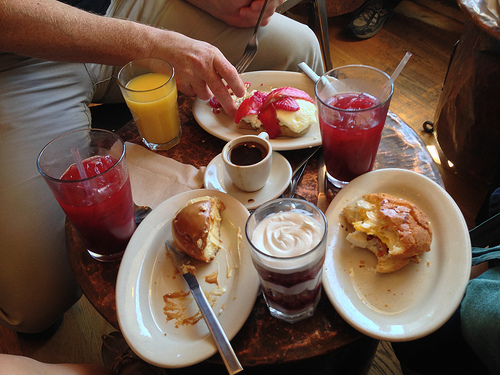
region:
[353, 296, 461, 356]
the plate is white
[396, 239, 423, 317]
the plate is white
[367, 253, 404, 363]
the plate is white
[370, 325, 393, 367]
the plate is white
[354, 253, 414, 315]
the plate is white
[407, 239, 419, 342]
the plate is white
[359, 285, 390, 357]
the plate is white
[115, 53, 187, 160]
A GLASS OR ORANGE JUICE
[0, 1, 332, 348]
THE MAN IS WEARING TAN PANTS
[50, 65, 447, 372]
THE TABLE IS SMALL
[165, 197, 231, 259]
THE DOUGHNUT IS HALF EATEN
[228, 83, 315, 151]
THE STRAWBERRIES ARE RED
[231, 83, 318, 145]
THE STRAWBERRIES ARE SLICED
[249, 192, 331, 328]
THE MILKSHAKE IS VANILLA AND CHOCOLAT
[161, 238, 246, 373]
THE KNIFE IS ON THE PLATE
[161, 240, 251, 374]
THE KNIFE IS DIRTY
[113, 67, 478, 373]
THE PLATES ARE OVAL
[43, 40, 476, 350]
food and drink on table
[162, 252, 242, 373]
silver knife on table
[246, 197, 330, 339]
milk shake on table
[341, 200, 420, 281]
sandwich on white plate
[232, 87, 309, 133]
pastry on white plate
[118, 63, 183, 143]
orange juice in glass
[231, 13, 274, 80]
silver fork in hand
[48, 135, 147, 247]
juice in clear glass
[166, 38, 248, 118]
hand of man eating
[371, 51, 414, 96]
clear straw in glass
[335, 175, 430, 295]
a half eaten sandwich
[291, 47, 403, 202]
tall glass of a red drink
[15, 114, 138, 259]
a glass with a straw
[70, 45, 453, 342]
wooden table full of food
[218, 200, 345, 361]
chocolate and vanilla swirled dessert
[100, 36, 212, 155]
glass of orange juice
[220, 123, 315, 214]
small mug of coffee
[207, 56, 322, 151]
plate of strawberry shortcake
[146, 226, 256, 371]
plain silver colored knife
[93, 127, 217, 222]
brown rectangular napkin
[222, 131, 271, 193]
small white cup of syrup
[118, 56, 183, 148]
clear glass with orange juice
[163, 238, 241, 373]
silver butter knife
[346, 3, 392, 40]
black and grey tennis shoe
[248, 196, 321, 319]
white and brown beverage in clear glass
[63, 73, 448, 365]
round brown table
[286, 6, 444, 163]
section of floor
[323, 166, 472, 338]
white plate with partially eaten pastry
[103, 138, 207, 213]
white napkin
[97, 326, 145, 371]
brown loafer